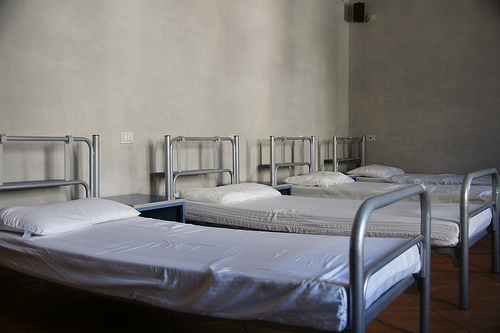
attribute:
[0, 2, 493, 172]
walls — grey, concrete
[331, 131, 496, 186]
bed — unoccupied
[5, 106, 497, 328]
beds covelets — white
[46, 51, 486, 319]
beds — empty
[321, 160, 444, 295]
iron — a headboard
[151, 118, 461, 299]
mattresses — plastic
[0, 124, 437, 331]
bed — unoccupied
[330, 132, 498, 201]
bed — unoccupied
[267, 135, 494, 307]
bed — unoccupied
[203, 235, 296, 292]
sheets — white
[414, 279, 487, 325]
floor — brown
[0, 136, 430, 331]
iron beds — gray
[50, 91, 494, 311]
beds — inside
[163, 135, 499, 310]
bed — unoccupied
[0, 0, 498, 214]
wall — white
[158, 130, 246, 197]
board — head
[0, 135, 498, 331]
beds — unmade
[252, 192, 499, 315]
flooring — brown, concrete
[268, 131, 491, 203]
bed — unoccupied